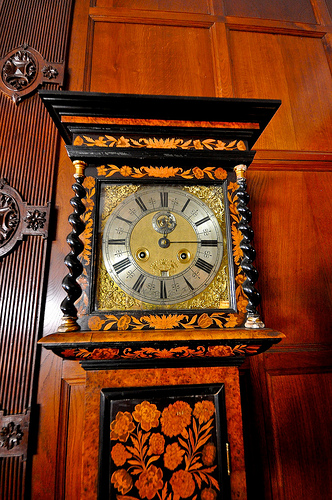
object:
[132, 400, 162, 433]
flower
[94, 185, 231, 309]
clock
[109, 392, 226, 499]
design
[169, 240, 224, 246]
hands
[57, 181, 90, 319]
spiral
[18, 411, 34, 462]
hinge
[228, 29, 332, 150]
panel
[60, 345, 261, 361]
carving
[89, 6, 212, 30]
frame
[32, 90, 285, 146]
board